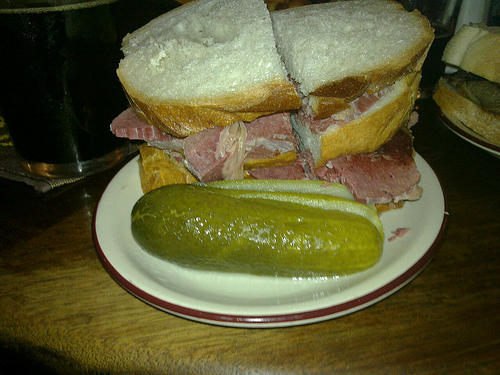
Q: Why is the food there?
A: So a person can eat it.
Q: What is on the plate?
A: A sandwich and pickle.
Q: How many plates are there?
A: Two.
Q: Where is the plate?
A: On the table.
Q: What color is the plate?
A: White.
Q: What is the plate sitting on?
A: A table.